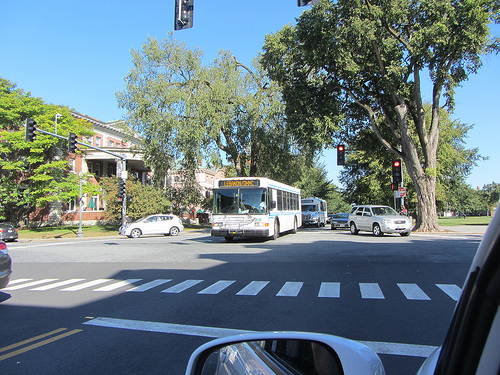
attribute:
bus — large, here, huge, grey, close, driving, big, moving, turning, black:
[195, 166, 320, 256]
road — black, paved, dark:
[177, 232, 427, 325]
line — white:
[150, 269, 255, 301]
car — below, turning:
[119, 206, 196, 254]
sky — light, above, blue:
[35, 2, 133, 103]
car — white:
[182, 197, 492, 372]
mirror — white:
[184, 327, 379, 372]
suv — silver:
[348, 199, 418, 233]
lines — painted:
[13, 270, 466, 306]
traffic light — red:
[335, 141, 347, 164]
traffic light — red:
[390, 156, 402, 187]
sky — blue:
[3, 3, 498, 188]